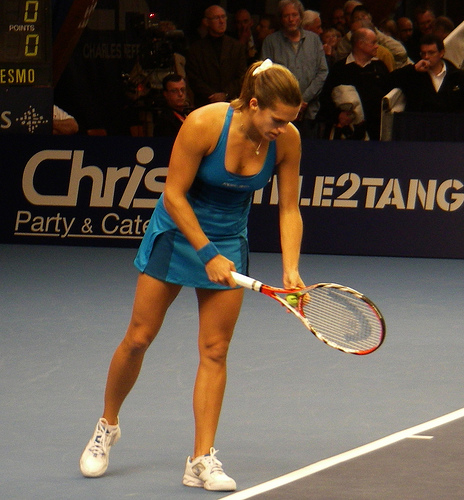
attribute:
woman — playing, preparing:
[79, 58, 303, 492]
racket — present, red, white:
[231, 271, 385, 355]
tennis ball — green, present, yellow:
[285, 286, 307, 309]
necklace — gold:
[239, 107, 264, 156]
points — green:
[23, 33, 39, 56]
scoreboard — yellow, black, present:
[0, 1, 55, 86]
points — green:
[23, 0, 39, 22]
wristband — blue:
[196, 240, 219, 263]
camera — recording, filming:
[140, 12, 187, 68]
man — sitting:
[154, 73, 188, 136]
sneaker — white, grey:
[183, 447, 238, 491]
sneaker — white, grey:
[78, 416, 120, 477]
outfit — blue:
[134, 103, 274, 289]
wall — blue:
[0, 132, 463, 261]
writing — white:
[14, 211, 150, 240]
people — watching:
[233, 0, 329, 137]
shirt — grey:
[260, 30, 328, 120]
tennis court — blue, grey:
[0, 244, 462, 499]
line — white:
[219, 407, 463, 498]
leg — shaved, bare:
[102, 272, 182, 425]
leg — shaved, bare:
[194, 286, 243, 458]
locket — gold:
[256, 150, 260, 156]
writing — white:
[21, 145, 169, 209]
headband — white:
[251, 57, 273, 74]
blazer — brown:
[185, 34, 247, 104]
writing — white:
[252, 173, 463, 212]